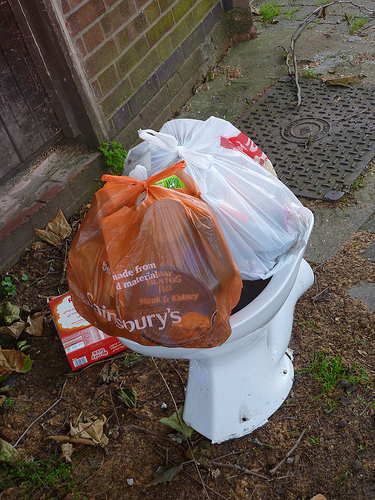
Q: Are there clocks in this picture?
A: No, there are no clocks.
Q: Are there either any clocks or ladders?
A: No, there are no clocks or ladders.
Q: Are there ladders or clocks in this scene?
A: No, there are no clocks or ladders.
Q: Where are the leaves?
A: The leaves are on the ground.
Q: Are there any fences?
A: No, there are no fences.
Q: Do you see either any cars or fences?
A: No, there are no fences or cars.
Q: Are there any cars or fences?
A: No, there are no fences or cars.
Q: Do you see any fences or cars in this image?
A: No, there are no fences or cars.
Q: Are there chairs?
A: No, there are no chairs.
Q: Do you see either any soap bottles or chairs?
A: No, there are no chairs or soap bottles.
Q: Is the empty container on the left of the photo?
A: Yes, the box is on the left of the image.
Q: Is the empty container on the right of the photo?
A: No, the box is on the left of the image.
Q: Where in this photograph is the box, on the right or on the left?
A: The box is on the left of the image.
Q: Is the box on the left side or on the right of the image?
A: The box is on the left of the image.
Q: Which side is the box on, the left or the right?
A: The box is on the left of the image.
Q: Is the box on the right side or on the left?
A: The box is on the left of the image.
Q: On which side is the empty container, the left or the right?
A: The box is on the left of the image.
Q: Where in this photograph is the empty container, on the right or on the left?
A: The box is on the left of the image.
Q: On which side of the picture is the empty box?
A: The box is on the left of the image.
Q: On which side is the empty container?
A: The box is on the left of the image.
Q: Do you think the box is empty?
A: Yes, the box is empty.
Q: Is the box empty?
A: Yes, the box is empty.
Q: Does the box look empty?
A: Yes, the box is empty.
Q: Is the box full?
A: No, the box is empty.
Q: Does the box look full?
A: No, the box is empty.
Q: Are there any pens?
A: No, there are no pens.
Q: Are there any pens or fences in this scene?
A: No, there are no pens or fences.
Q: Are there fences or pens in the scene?
A: No, there are no pens or fences.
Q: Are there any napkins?
A: No, there are no napkins.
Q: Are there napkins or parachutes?
A: No, there are no napkins or parachutes.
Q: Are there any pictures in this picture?
A: No, there are no pictures.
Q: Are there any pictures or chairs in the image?
A: No, there are no pictures or chairs.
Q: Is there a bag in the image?
A: Yes, there is a bag.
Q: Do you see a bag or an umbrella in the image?
A: Yes, there is a bag.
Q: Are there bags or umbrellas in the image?
A: Yes, there is a bag.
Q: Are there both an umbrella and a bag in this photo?
A: No, there is a bag but no umbrellas.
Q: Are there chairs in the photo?
A: No, there are no chairs.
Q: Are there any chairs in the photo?
A: No, there are no chairs.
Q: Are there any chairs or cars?
A: No, there are no chairs or cars.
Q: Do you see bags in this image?
A: Yes, there is a bag.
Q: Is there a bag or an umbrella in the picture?
A: Yes, there is a bag.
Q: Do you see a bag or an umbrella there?
A: Yes, there is a bag.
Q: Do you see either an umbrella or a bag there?
A: Yes, there is a bag.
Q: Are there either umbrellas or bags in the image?
A: Yes, there is a bag.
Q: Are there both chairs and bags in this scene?
A: No, there is a bag but no chairs.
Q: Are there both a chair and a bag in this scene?
A: No, there is a bag but no chairs.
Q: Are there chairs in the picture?
A: No, there are no chairs.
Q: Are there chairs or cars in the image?
A: No, there are no chairs or cars.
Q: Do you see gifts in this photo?
A: No, there are no gifts.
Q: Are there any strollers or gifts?
A: No, there are no gifts or strollers.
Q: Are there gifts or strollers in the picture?
A: No, there are no gifts or strollers.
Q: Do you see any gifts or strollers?
A: No, there are no gifts or strollers.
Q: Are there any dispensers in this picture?
A: No, there are no dispensers.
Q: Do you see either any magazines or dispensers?
A: No, there are no dispensers or magazines.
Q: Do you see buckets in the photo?
A: No, there are no buckets.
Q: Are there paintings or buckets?
A: No, there are no buckets or paintings.